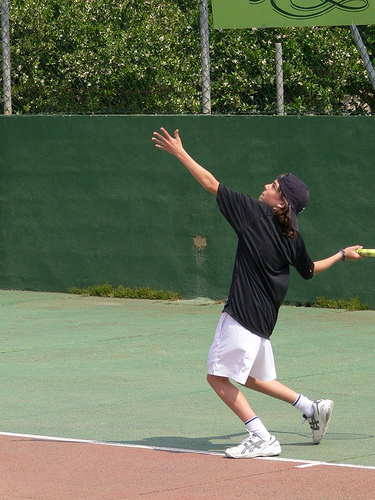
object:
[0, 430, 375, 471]
line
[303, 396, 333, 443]
shoe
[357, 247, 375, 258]
grip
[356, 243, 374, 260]
racket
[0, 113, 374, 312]
wall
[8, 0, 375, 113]
bushes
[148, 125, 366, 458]
woman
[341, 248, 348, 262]
watchband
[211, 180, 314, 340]
black shirt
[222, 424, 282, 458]
foot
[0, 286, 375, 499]
court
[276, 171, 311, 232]
hat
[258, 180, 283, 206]
face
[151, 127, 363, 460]
boy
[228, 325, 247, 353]
ball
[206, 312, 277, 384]
short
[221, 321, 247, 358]
pocket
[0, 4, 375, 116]
trees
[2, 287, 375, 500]
tennis court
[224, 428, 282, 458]
shoe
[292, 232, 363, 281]
right arm